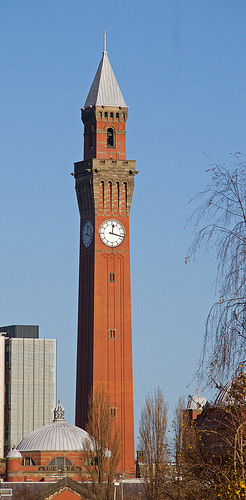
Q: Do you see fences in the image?
A: No, there are no fences.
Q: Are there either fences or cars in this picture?
A: No, there are no fences or cars.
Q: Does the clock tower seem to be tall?
A: Yes, the tower is tall.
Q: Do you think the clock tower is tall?
A: Yes, the tower is tall.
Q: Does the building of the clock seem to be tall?
A: Yes, the tower is tall.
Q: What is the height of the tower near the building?
A: The tower is tall.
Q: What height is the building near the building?
A: The tower is tall.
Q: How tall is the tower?
A: The tower is tall.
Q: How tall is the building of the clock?
A: The tower is tall.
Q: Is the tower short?
A: No, the tower is tall.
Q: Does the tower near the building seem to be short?
A: No, the tower is tall.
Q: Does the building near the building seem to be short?
A: No, the tower is tall.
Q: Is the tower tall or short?
A: The tower is tall.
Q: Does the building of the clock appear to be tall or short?
A: The tower is tall.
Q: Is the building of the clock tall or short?
A: The tower is tall.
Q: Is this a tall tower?
A: Yes, this is a tall tower.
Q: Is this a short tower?
A: No, this is a tall tower.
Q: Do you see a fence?
A: No, there are no fences.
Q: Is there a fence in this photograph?
A: No, there are no fences.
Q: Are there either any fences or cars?
A: No, there are no fences or cars.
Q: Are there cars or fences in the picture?
A: No, there are no fences or cars.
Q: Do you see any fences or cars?
A: No, there are no fences or cars.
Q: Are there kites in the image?
A: No, there are no kites.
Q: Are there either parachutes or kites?
A: No, there are no kites or parachutes.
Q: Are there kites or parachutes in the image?
A: No, there are no kites or parachutes.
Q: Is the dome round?
A: Yes, the dome is round.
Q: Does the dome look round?
A: Yes, the dome is round.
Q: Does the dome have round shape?
A: Yes, the dome is round.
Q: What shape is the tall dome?
A: The dome is round.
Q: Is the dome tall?
A: Yes, the dome is tall.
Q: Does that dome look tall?
A: Yes, the dome is tall.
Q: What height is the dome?
A: The dome is tall.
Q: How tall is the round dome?
A: The dome is tall.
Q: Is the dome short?
A: No, the dome is tall.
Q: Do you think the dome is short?
A: No, the dome is tall.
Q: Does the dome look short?
A: No, the dome is tall.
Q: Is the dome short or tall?
A: The dome is tall.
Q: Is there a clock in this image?
A: Yes, there is a clock.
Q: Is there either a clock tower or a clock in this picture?
A: Yes, there is a clock.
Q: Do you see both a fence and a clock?
A: No, there is a clock but no fences.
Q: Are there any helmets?
A: No, there are no helmets.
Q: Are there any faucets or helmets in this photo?
A: No, there are no helmets or faucets.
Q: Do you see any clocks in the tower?
A: Yes, there is a clock in the tower.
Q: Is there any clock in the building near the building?
A: Yes, there is a clock in the tower.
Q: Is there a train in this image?
A: No, there are no trains.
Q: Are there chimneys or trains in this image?
A: No, there are no trains or chimneys.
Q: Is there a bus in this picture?
A: No, there are no buses.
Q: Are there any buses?
A: No, there are no buses.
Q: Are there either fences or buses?
A: No, there are no buses or fences.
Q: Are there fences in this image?
A: No, there are no fences.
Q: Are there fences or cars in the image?
A: No, there are no fences or cars.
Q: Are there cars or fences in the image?
A: No, there are no fences or cars.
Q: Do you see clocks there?
A: Yes, there is a clock.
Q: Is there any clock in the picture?
A: Yes, there is a clock.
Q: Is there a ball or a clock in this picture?
A: Yes, there is a clock.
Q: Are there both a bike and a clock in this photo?
A: No, there is a clock but no bikes.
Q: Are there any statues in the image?
A: No, there are no statues.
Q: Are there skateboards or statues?
A: No, there are no statues or skateboards.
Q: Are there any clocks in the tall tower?
A: Yes, there is a clock in the tower.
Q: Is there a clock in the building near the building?
A: Yes, there is a clock in the tower.